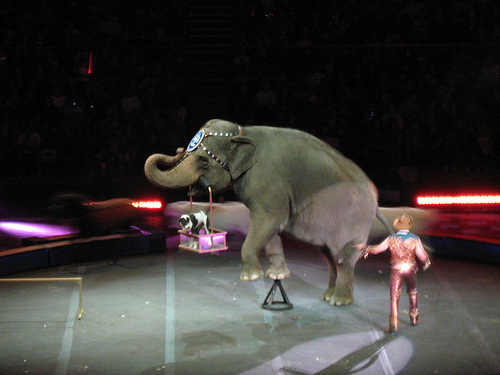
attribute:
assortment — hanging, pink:
[178, 192, 226, 254]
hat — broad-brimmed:
[391, 213, 415, 231]